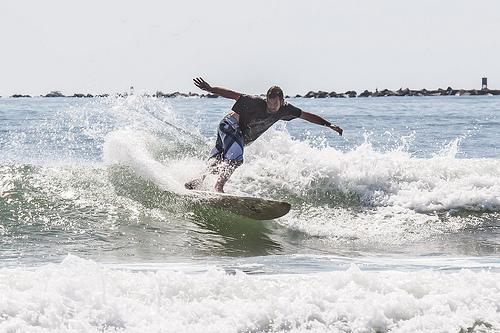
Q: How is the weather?
A: It is cloudy.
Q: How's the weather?
A: It is cloudy.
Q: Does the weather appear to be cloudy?
A: Yes, it is cloudy.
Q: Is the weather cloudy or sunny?
A: It is cloudy.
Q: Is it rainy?
A: No, it is cloudy.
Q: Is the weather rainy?
A: No, it is cloudy.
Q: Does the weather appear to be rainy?
A: No, it is cloudy.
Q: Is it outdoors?
A: Yes, it is outdoors.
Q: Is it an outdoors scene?
A: Yes, it is outdoors.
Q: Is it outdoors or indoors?
A: It is outdoors.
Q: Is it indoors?
A: No, it is outdoors.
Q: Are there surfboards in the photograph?
A: Yes, there is a surfboard.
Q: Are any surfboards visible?
A: Yes, there is a surfboard.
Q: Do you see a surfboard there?
A: Yes, there is a surfboard.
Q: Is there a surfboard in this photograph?
A: Yes, there is a surfboard.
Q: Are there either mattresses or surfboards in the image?
A: Yes, there is a surfboard.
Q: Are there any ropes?
A: No, there are no ropes.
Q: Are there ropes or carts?
A: No, there are no ropes or carts.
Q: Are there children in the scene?
A: No, there are no children.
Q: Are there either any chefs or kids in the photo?
A: No, there are no kids or chefs.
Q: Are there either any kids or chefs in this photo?
A: No, there are no kids or chefs.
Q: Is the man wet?
A: Yes, the man is wet.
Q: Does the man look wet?
A: Yes, the man is wet.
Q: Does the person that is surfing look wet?
A: Yes, the man is wet.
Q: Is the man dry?
A: No, the man is wet.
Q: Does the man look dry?
A: No, the man is wet.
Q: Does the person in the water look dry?
A: No, the man is wet.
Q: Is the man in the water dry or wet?
A: The man is wet.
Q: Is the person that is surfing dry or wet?
A: The man is wet.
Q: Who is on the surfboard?
A: The man is on the surfboard.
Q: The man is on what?
A: The man is on the surf board.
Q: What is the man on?
A: The man is on the surf board.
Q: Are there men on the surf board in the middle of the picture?
A: Yes, there is a man on the surfboard.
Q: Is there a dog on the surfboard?
A: No, there is a man on the surfboard.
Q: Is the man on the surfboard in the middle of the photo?
A: Yes, the man is on the surfboard.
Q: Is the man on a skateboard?
A: No, the man is on the surfboard.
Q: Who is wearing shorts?
A: The man is wearing shorts.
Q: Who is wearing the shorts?
A: The man is wearing shorts.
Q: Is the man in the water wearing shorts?
A: Yes, the man is wearing shorts.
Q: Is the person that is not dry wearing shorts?
A: Yes, the man is wearing shorts.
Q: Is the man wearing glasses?
A: No, the man is wearing shorts.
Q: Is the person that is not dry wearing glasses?
A: No, the man is wearing shorts.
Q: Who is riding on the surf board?
A: The man is riding on the surf board.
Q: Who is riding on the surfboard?
A: The man is riding on the surf board.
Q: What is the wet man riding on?
A: The man is riding on the surfboard.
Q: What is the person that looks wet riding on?
A: The man is riding on the surfboard.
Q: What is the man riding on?
A: The man is riding on the surfboard.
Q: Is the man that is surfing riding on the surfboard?
A: Yes, the man is riding on the surfboard.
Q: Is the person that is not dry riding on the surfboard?
A: Yes, the man is riding on the surfboard.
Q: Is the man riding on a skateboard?
A: No, the man is riding on the surfboard.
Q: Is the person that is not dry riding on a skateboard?
A: No, the man is riding on the surfboard.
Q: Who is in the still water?
A: The man is in the water.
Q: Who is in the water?
A: The man is in the water.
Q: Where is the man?
A: The man is in the water.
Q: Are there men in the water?
A: Yes, there is a man in the water.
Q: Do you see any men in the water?
A: Yes, there is a man in the water.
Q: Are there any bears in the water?
A: No, there is a man in the water.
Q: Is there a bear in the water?
A: No, there is a man in the water.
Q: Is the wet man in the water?
A: Yes, the man is in the water.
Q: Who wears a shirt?
A: The man wears a shirt.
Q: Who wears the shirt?
A: The man wears a shirt.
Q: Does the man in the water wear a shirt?
A: Yes, the man wears a shirt.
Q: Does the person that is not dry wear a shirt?
A: Yes, the man wears a shirt.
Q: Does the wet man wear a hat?
A: No, the man wears a shirt.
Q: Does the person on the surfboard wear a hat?
A: No, the man wears a shirt.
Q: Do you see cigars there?
A: No, there are no cigars.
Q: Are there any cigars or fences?
A: No, there are no cigars or fences.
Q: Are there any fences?
A: No, there are no fences.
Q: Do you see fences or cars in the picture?
A: No, there are no fences or cars.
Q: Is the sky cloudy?
A: Yes, the sky is cloudy.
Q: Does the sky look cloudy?
A: Yes, the sky is cloudy.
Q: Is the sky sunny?
A: No, the sky is cloudy.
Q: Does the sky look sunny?
A: No, the sky is cloudy.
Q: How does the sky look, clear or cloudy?
A: The sky is cloudy.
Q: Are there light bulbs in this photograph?
A: No, there are no light bulbs.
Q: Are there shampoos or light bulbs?
A: No, there are no light bulbs or shampoos.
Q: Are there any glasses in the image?
A: No, there are no glasses.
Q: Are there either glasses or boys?
A: No, there are no glasses or boys.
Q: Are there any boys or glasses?
A: No, there are no glasses or boys.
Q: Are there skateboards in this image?
A: No, there are no skateboards.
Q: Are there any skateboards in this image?
A: No, there are no skateboards.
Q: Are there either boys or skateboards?
A: No, there are no skateboards or boys.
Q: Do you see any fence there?
A: No, there are no fences.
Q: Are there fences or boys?
A: No, there are no fences or boys.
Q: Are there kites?
A: No, there are no kites.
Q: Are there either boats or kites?
A: No, there are no kites or boats.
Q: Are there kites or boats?
A: No, there are no kites or boats.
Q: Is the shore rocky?
A: Yes, the shore is rocky.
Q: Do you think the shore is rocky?
A: Yes, the shore is rocky.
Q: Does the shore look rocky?
A: Yes, the shore is rocky.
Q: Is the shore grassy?
A: No, the shore is rocky.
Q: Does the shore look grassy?
A: No, the shore is rocky.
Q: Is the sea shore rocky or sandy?
A: The sea shore is rocky.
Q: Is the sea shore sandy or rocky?
A: The sea shore is rocky.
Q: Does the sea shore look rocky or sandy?
A: The sea shore is rocky.